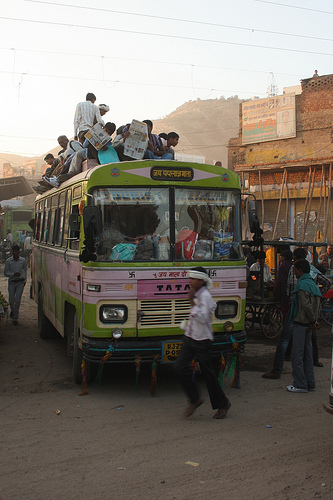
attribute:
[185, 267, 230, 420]
man — wearing white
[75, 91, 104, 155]
man — wearing white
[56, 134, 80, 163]
man — wearing white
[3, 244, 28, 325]
man — wearing white